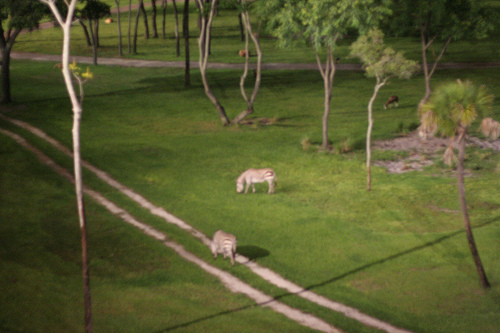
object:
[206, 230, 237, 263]
zebras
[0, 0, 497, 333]
grass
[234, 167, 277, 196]
zebra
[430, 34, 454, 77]
branch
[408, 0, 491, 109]
tree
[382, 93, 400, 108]
animal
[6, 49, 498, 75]
road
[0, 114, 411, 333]
tracks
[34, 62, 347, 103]
shadows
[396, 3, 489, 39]
leaves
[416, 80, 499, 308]
tree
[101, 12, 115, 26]
rock